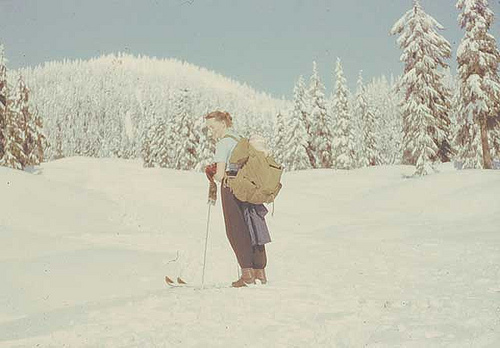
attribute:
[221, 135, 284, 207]
bag — brown, green, large 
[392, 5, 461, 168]
tree — covered, green, tall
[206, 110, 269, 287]
woman — standing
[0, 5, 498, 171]
trees — covered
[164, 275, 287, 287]
skii — for skiing, bent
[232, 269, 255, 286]
boot — brown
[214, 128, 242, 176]
shirt — white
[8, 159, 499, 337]
snow — white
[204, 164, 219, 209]
scarf — red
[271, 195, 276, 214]
strap — hanging